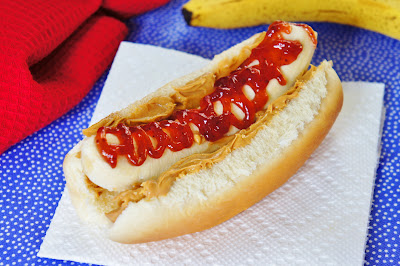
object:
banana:
[78, 20, 319, 192]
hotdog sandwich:
[56, 20, 342, 239]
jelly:
[183, 67, 273, 139]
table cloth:
[0, 0, 397, 264]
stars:
[1, 1, 395, 264]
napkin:
[33, 40, 386, 266]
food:
[61, 0, 400, 243]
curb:
[36, 13, 400, 259]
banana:
[179, 0, 400, 44]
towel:
[0, 0, 171, 154]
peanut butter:
[96, 19, 303, 168]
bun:
[61, 20, 344, 245]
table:
[0, 0, 399, 266]